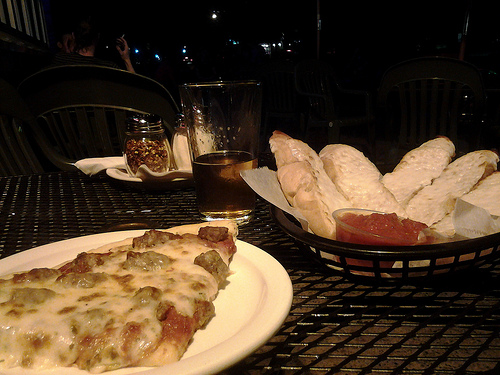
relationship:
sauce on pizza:
[9, 259, 217, 349] [7, 216, 247, 373]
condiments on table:
[85, 70, 282, 220] [6, 148, 499, 360]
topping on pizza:
[56, 269, 108, 289] [79, 141, 291, 344]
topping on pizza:
[56, 269, 108, 289] [0, 216, 240, 374]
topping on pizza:
[56, 269, 108, 289] [58, 157, 222, 359]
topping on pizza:
[56, 269, 108, 289] [7, 216, 247, 373]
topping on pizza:
[92, 283, 165, 323] [63, 256, 224, 352]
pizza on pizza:
[0, 216, 240, 374] [18, 212, 261, 372]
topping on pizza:
[56, 269, 108, 289] [25, 216, 243, 363]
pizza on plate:
[0, 216, 240, 374] [0, 210, 295, 373]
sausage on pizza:
[200, 246, 227, 282] [7, 216, 247, 373]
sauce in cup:
[333, 212, 429, 272] [330, 203, 430, 274]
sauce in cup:
[329, 206, 429, 273] [323, 200, 426, 259]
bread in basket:
[272, 133, 498, 235] [272, 197, 497, 281]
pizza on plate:
[7, 216, 247, 373] [0, 229, 295, 373]